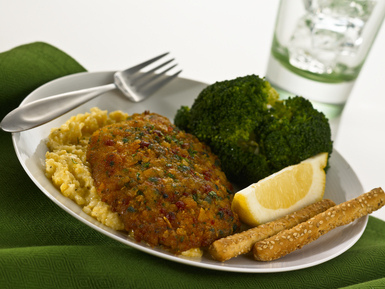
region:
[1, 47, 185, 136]
fork placed in a white plate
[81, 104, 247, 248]
piece of vegetable cutlet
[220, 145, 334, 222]
piece of sliced lemon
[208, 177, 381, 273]
two pieces of breadsticks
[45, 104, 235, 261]
cooked egg under the cutlet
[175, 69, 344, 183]
steamed broccoli in the plate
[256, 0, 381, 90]
glass of water with ice in it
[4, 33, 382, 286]
green table cloth under the plate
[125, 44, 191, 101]
four prongs on the fork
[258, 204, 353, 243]
seeds on the breadstick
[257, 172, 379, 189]
Cut up slice of lemon on the plate.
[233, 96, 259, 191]
Cut up slice of lemon on the plate.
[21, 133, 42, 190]
there is a plate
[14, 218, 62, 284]
there is a green table mat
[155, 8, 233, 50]
the background is white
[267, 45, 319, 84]
there is a glass in the background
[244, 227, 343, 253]
there are pretzel sticks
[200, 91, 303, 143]
there is someting green